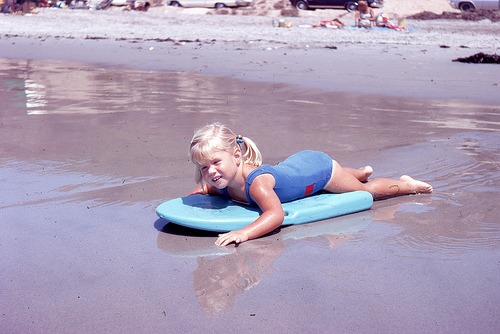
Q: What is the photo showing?
A: It is showing a beach.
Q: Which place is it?
A: It is a beach.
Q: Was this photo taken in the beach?
A: Yes, it was taken in the beach.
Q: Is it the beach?
A: Yes, it is the beach.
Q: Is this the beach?
A: Yes, it is the beach.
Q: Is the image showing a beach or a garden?
A: It is showing a beach.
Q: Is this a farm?
A: No, it is a beach.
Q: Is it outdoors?
A: Yes, it is outdoors.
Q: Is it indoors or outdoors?
A: It is outdoors.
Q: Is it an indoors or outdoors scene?
A: It is outdoors.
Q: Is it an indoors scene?
A: No, it is outdoors.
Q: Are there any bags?
A: No, there are no bags.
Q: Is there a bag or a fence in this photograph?
A: No, there are no bags or fences.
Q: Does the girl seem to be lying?
A: Yes, the girl is lying.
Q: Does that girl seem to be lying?
A: Yes, the girl is lying.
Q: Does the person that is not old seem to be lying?
A: Yes, the girl is lying.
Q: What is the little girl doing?
A: The girl is lying.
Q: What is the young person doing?
A: The girl is lying.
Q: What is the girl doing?
A: The girl is lying.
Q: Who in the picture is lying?
A: The girl is lying.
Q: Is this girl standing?
A: No, the girl is lying.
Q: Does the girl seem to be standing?
A: No, the girl is lying.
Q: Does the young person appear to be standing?
A: No, the girl is lying.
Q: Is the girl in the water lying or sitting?
A: The girl is lying.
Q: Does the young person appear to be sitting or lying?
A: The girl is lying.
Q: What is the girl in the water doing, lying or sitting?
A: The girl is lying.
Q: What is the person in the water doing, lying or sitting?
A: The girl is lying.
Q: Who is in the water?
A: The girl is in the water.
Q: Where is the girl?
A: The girl is in the water.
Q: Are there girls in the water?
A: Yes, there is a girl in the water.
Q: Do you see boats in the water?
A: No, there is a girl in the water.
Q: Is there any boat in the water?
A: No, there is a girl in the water.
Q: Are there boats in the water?
A: No, there is a girl in the water.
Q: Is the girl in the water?
A: Yes, the girl is in the water.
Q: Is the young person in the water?
A: Yes, the girl is in the water.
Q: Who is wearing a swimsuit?
A: The girl is wearing a swimsuit.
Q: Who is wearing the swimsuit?
A: The girl is wearing a swimsuit.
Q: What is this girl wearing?
A: The girl is wearing a swimsuit.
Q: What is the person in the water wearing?
A: The girl is wearing a swimsuit.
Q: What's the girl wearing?
A: The girl is wearing a swimsuit.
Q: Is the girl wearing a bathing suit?
A: Yes, the girl is wearing a bathing suit.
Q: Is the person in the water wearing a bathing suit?
A: Yes, the girl is wearing a bathing suit.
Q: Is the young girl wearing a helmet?
A: No, the girl is wearing a bathing suit.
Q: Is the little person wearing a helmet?
A: No, the girl is wearing a bathing suit.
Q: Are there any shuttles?
A: No, there are no shuttles.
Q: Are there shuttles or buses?
A: No, there are no shuttles or buses.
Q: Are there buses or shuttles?
A: No, there are no shuttles or buses.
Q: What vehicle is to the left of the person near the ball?
A: The vehicle is a car.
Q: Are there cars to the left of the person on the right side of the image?
A: Yes, there is a car to the left of the person.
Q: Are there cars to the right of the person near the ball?
A: No, the car is to the left of the person.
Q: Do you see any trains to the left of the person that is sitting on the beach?
A: No, there is a car to the left of the person.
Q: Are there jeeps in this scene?
A: No, there are no jeeps.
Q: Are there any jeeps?
A: No, there are no jeeps.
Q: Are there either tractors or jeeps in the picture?
A: No, there are no jeeps or tractors.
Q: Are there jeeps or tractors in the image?
A: No, there are no jeeps or tractors.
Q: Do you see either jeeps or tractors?
A: No, there are no jeeps or tractors.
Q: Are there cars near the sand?
A: Yes, there is a car near the sand.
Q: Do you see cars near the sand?
A: Yes, there is a car near the sand.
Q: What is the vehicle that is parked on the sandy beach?
A: The vehicle is a car.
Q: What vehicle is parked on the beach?
A: The vehicle is a car.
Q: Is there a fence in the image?
A: No, there are no fences.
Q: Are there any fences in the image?
A: No, there are no fences.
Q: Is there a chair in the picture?
A: No, there are no chairs.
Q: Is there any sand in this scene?
A: Yes, there is sand.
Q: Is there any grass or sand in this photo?
A: Yes, there is sand.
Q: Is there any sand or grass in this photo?
A: Yes, there is sand.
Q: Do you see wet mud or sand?
A: Yes, there is wet sand.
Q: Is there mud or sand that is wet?
A: Yes, the sand is wet.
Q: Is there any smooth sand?
A: Yes, there is smooth sand.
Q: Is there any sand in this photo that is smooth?
A: Yes, there is sand that is smooth.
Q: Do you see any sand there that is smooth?
A: Yes, there is sand that is smooth.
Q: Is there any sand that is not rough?
A: Yes, there is smooth sand.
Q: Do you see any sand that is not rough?
A: Yes, there is smooth sand.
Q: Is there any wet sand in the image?
A: Yes, there is wet sand.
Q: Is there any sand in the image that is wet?
A: Yes, there is sand that is wet.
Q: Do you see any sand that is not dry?
A: Yes, there is wet sand.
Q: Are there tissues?
A: No, there are no tissues.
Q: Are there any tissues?
A: No, there are no tissues.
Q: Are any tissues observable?
A: No, there are no tissues.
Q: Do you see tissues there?
A: No, there are no tissues.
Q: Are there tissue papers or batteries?
A: No, there are no tissue papers or batteries.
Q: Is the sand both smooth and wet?
A: Yes, the sand is smooth and wet.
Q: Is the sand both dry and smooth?
A: No, the sand is smooth but wet.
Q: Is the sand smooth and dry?
A: No, the sand is smooth but wet.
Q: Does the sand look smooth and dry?
A: No, the sand is smooth but wet.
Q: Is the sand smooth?
A: Yes, the sand is smooth.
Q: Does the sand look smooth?
A: Yes, the sand is smooth.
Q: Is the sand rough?
A: No, the sand is smooth.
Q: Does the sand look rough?
A: No, the sand is smooth.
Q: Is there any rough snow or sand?
A: No, there is sand but it is smooth.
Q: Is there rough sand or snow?
A: No, there is sand but it is smooth.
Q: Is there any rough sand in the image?
A: No, there is sand but it is smooth.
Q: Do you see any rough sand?
A: No, there is sand but it is smooth.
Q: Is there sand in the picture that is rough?
A: No, there is sand but it is smooth.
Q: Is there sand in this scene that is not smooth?
A: No, there is sand but it is smooth.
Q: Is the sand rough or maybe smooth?
A: The sand is smooth.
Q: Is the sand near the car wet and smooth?
A: Yes, the sand is wet and smooth.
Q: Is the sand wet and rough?
A: No, the sand is wet but smooth.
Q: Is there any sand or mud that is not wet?
A: No, there is sand but it is wet.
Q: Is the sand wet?
A: Yes, the sand is wet.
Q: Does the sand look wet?
A: Yes, the sand is wet.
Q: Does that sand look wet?
A: Yes, the sand is wet.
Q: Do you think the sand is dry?
A: No, the sand is wet.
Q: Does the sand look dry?
A: No, the sand is wet.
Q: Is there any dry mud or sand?
A: No, there is sand but it is wet.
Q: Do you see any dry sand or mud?
A: No, there is sand but it is wet.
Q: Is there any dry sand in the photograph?
A: No, there is sand but it is wet.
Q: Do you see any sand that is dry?
A: No, there is sand but it is wet.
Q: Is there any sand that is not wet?
A: No, there is sand but it is wet.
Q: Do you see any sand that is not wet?
A: No, there is sand but it is wet.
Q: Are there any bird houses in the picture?
A: No, there are no bird houses.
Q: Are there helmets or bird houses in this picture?
A: No, there are no bird houses or helmets.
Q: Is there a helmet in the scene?
A: No, there are no helmets.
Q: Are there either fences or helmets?
A: No, there are no helmets or fences.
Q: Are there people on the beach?
A: Yes, there is a person on the beach.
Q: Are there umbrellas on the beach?
A: No, there is a person on the beach.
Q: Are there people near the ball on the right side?
A: Yes, there is a person near the ball.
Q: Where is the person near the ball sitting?
A: The person is sitting on the beach.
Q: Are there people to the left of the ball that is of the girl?
A: Yes, there is a person to the left of the ball.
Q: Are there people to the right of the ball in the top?
A: No, the person is to the left of the ball.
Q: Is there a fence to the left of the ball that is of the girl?
A: No, there is a person to the left of the ball.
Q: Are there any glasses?
A: No, there are no glasses.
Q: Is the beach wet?
A: Yes, the beach is wet.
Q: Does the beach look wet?
A: Yes, the beach is wet.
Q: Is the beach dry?
A: No, the beach is wet.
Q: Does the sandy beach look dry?
A: No, the beach is wet.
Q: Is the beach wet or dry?
A: The beach is wet.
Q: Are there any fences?
A: No, there are no fences.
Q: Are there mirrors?
A: No, there are no mirrors.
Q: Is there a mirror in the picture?
A: No, there are no mirrors.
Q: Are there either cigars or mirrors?
A: No, there are no mirrors or cigars.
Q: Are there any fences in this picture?
A: No, there are no fences.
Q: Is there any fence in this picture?
A: No, there are no fences.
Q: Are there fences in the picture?
A: No, there are no fences.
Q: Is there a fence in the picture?
A: No, there are no fences.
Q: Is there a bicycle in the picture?
A: No, there are no bicycles.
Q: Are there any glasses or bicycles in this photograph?
A: No, there are no bicycles or glasses.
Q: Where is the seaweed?
A: The seaweed is on the beach.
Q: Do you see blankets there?
A: Yes, there is a blanket.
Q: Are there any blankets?
A: Yes, there is a blanket.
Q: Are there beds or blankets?
A: Yes, there is a blanket.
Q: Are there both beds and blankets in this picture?
A: No, there is a blanket but no beds.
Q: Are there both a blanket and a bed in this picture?
A: No, there is a blanket but no beds.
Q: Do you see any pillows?
A: No, there are no pillows.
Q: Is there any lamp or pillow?
A: No, there are no pillows or lamps.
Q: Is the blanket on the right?
A: Yes, the blanket is on the right of the image.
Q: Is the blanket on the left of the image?
A: No, the blanket is on the right of the image.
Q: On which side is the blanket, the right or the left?
A: The blanket is on the right of the image.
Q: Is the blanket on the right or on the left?
A: The blanket is on the right of the image.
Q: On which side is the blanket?
A: The blanket is on the right of the image.